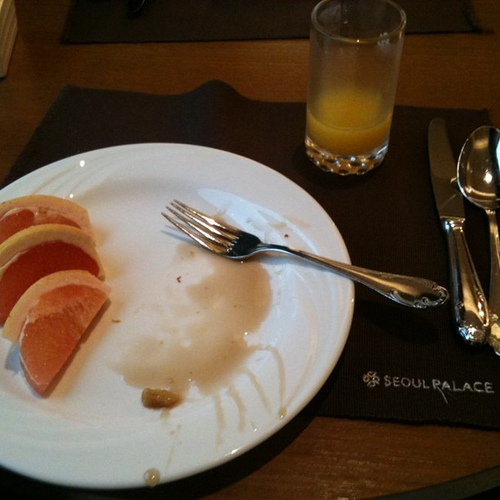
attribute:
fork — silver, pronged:
[164, 200, 449, 310]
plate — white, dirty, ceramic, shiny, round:
[0, 142, 356, 491]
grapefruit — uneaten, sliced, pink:
[0, 193, 111, 394]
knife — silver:
[428, 116, 488, 347]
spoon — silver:
[457, 122, 499, 357]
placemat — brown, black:
[1, 78, 500, 429]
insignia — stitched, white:
[363, 370, 495, 395]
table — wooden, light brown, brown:
[0, 0, 499, 499]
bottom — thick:
[303, 132, 390, 176]